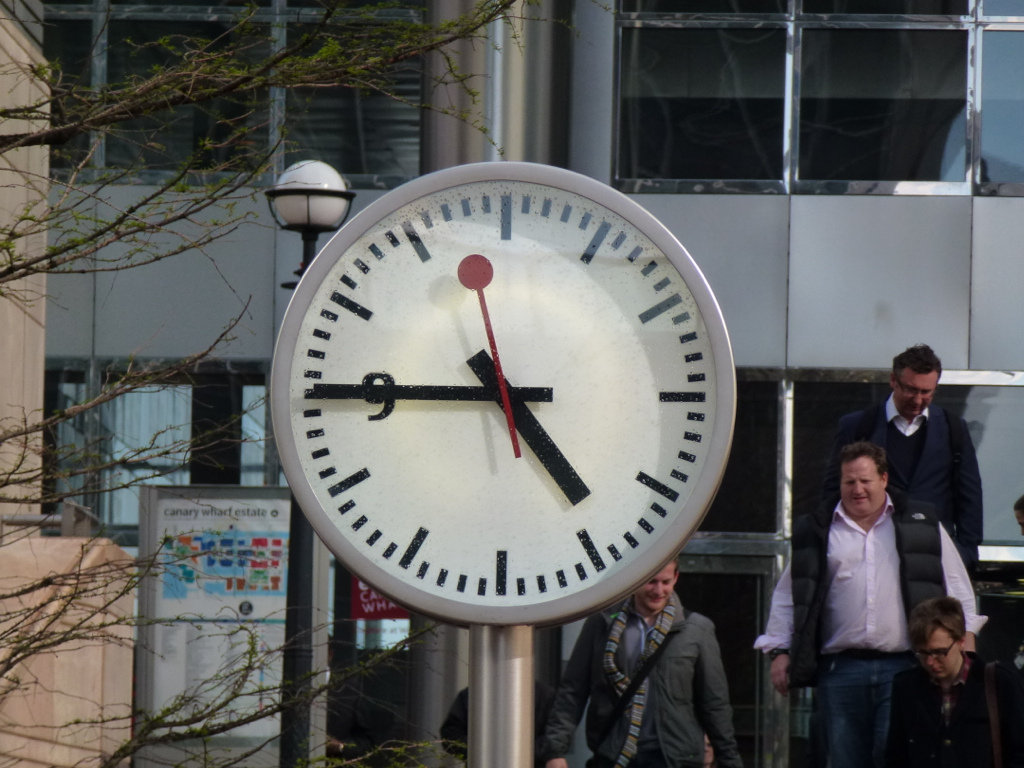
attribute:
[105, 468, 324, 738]
sign — white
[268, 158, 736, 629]
clock — black, white